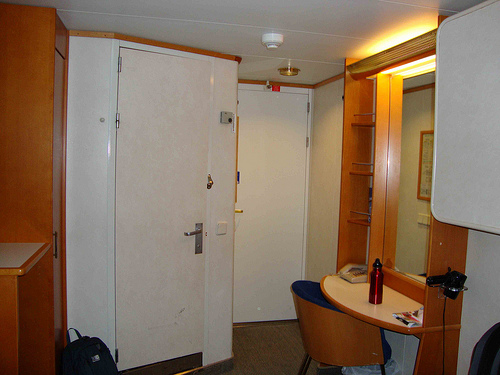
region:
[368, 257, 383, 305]
the red bottle on the desk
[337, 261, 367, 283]
the phone on the desk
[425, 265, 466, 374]
the hair dryer hanging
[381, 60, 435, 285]
the mirror on the wall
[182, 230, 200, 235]
the silver handle on the door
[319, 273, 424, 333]
the desk in front of the mirror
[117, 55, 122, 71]
the hinge on the door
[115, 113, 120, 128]
the hinge on the door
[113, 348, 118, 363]
the hinge on the door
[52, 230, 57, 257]
the handle on the door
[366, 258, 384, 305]
A red water bottle.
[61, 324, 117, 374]
Part of a blue backpack.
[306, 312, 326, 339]
Part of a chair.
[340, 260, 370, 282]
Part of a white phone.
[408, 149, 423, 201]
Part of the mirror.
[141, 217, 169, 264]
part of a door.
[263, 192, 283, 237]
Part of a white door.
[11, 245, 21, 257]
Part of the counter.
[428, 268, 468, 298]
A black hairdryer on the wall.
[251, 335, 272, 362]
Part of the floor.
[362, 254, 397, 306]
water bottle on a bus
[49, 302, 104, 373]
backpack on the floor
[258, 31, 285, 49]
smoke detector on the ceiling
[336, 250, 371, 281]
phone on the desk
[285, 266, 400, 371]
blue chair under the desk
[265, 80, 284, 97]
red sticker on the wall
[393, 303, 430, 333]
book on the table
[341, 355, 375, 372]
garbage can under the city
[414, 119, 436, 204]
picture on a wall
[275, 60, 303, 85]
light on the ceiling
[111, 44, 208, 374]
The white interior door.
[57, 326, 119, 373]
A black book bag.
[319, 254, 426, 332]
A lightly colored desk.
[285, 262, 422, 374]
A chair is pushed under a desk.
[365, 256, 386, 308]
Metallic red bottle with a black lid.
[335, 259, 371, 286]
An outdated, dark beige phone.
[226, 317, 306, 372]
The floor is carpeted.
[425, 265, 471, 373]
A black device with a black cord.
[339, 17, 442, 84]
A light is on near the ceiling.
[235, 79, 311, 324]
The exit door is white.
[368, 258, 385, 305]
a red bottle with a black top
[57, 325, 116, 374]
a black backpack on the floor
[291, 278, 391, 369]
a wooden chair with a blue cushion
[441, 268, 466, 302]
a black landline phone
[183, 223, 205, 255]
a silver handle on a door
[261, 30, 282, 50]
a white fire alarm on the ceiling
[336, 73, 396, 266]
a wooden shelf against the wall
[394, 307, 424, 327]
papers on a desk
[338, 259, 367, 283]
a beige landline phone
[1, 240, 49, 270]
a white shelf